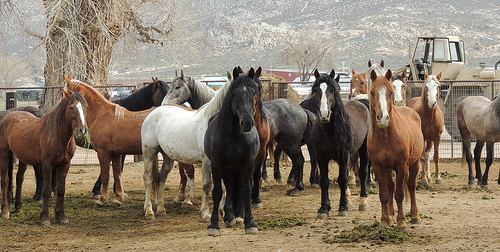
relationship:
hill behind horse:
[184, 7, 454, 34] [363, 68, 426, 228]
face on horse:
[368, 64, 395, 131] [366, 68, 423, 232]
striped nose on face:
[379, 86, 388, 117] [368, 64, 395, 131]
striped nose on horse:
[379, 86, 388, 117] [366, 68, 423, 232]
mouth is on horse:
[74, 127, 89, 144] [0, 86, 94, 231]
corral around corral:
[2, 62, 500, 252] [2, 62, 500, 252]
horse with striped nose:
[365, 64, 421, 227] [368, 81, 390, 130]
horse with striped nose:
[417, 69, 444, 181] [423, 76, 439, 109]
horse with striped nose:
[392, 69, 414, 113] [390, 71, 403, 103]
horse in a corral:
[366, 69, 424, 233] [2, 62, 497, 250]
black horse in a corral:
[202, 71, 265, 237] [0, 83, 499, 250]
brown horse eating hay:
[1, 97, 96, 226] [64, 189, 93, 221]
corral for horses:
[2, 62, 500, 252] [12, 70, 491, 179]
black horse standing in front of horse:
[203, 67, 261, 236] [140, 73, 233, 214]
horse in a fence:
[366, 69, 424, 233] [0, 85, 498, 157]